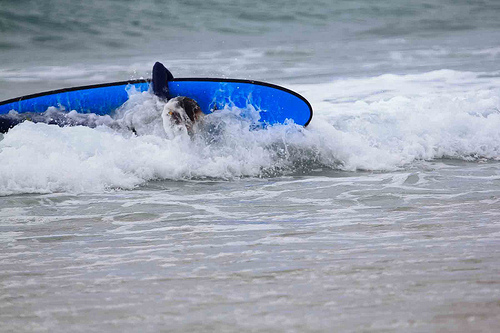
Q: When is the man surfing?
A: Daytime.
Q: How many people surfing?
A: One.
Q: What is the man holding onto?
A: Surfboard.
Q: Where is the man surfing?
A: Ocean.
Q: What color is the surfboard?
A: Black and blue.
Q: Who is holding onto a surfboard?
A: A man.